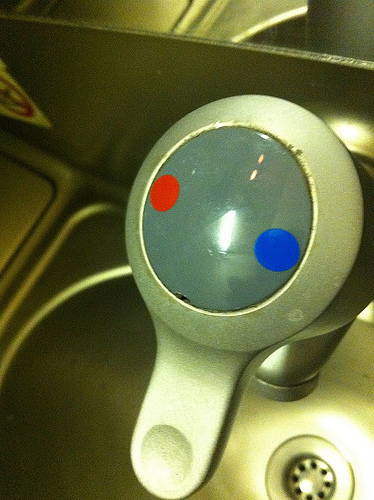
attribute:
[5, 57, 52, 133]
sign — white, red 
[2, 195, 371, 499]
sink — stainless steel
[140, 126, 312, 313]
circular insert — grey